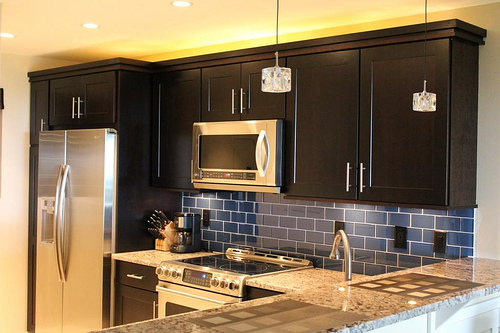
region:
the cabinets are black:
[8, 36, 495, 245]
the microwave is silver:
[178, 121, 304, 210]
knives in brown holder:
[144, 191, 173, 244]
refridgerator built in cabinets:
[18, 120, 108, 330]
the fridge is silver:
[21, 131, 128, 328]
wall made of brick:
[175, 189, 491, 287]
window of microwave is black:
[199, 134, 273, 176]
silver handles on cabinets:
[335, 149, 375, 199]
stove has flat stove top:
[185, 240, 296, 302]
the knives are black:
[139, 205, 181, 241]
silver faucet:
[311, 210, 382, 272]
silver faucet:
[291, 222, 403, 307]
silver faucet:
[324, 224, 382, 306]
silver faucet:
[295, 211, 355, 311]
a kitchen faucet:
[324, 230, 370, 286]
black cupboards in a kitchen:
[277, 14, 486, 212]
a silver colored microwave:
[184, 110, 290, 192]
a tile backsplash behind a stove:
[169, 193, 458, 268]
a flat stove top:
[176, 241, 297, 298]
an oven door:
[151, 283, 230, 316]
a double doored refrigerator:
[35, 123, 124, 332]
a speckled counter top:
[101, 251, 496, 331]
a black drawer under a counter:
[109, 255, 166, 297]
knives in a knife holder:
[141, 204, 175, 252]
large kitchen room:
[0, 25, 488, 265]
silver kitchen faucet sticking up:
[328, 200, 375, 278]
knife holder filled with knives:
[145, 185, 177, 259]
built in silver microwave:
[154, 85, 295, 213]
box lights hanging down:
[257, 57, 294, 99]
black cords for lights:
[242, 1, 287, 65]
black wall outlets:
[384, 201, 421, 258]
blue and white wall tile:
[77, 204, 368, 254]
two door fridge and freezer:
[5, 122, 117, 330]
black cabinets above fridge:
[25, 60, 119, 137]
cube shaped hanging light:
[255, 56, 300, 102]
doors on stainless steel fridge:
[25, 124, 119, 316]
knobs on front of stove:
[147, 262, 241, 293]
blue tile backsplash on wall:
[247, 204, 314, 238]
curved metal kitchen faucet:
[317, 226, 359, 281]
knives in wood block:
[141, 205, 180, 256]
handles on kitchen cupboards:
[335, 155, 372, 199]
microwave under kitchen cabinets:
[182, 115, 279, 194]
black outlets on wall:
[385, 219, 451, 258]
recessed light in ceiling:
[71, 14, 121, 40]